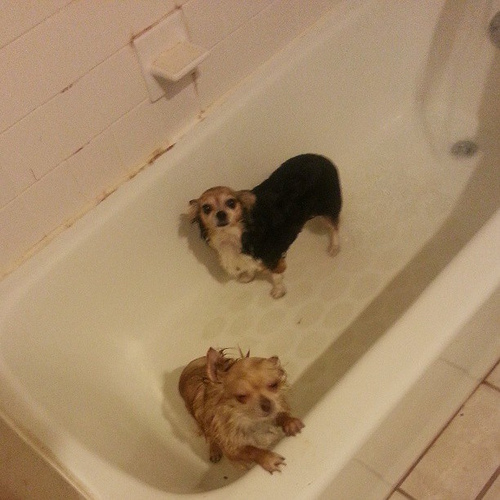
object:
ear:
[236, 189, 257, 210]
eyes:
[225, 198, 237, 210]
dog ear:
[205, 346, 229, 383]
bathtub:
[0, 0, 500, 500]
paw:
[282, 417, 306, 437]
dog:
[178, 345, 306, 476]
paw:
[269, 283, 287, 299]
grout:
[125, 141, 176, 181]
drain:
[451, 140, 478, 161]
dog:
[187, 153, 344, 300]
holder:
[132, 7, 211, 101]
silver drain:
[450, 139, 479, 159]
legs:
[270, 254, 288, 300]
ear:
[266, 355, 281, 368]